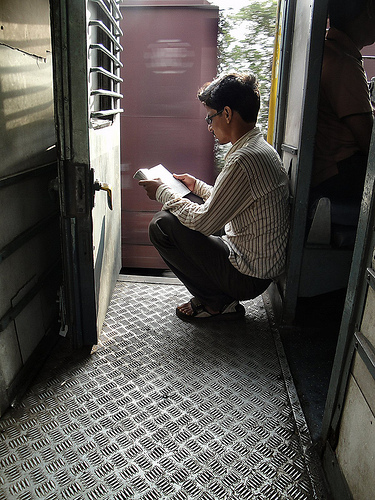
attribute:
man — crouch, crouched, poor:
[127, 57, 305, 335]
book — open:
[126, 156, 200, 204]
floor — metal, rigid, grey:
[27, 258, 316, 499]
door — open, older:
[42, 0, 147, 354]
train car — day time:
[8, 4, 374, 496]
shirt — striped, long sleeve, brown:
[154, 126, 301, 284]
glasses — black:
[199, 103, 242, 125]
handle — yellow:
[90, 167, 120, 218]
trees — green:
[217, 8, 278, 85]